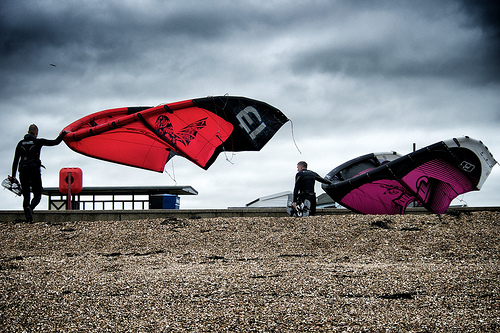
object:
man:
[4, 123, 65, 222]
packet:
[0, 176, 24, 197]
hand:
[10, 176, 17, 182]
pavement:
[1, 207, 289, 219]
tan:
[0, 206, 499, 220]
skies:
[0, 1, 500, 211]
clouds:
[0, 3, 500, 100]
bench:
[41, 182, 200, 209]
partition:
[75, 195, 85, 202]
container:
[58, 166, 84, 196]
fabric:
[59, 94, 289, 174]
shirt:
[10, 132, 65, 177]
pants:
[15, 172, 43, 216]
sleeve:
[43, 134, 63, 147]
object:
[322, 135, 496, 216]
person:
[290, 158, 334, 220]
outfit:
[285, 170, 332, 217]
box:
[161, 194, 182, 209]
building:
[245, 190, 340, 208]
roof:
[244, 189, 330, 207]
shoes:
[20, 218, 35, 224]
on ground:
[2, 207, 500, 332]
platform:
[0, 203, 500, 219]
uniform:
[10, 133, 67, 216]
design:
[234, 104, 270, 140]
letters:
[234, 104, 267, 141]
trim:
[322, 148, 379, 186]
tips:
[448, 134, 500, 190]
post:
[67, 172, 73, 210]